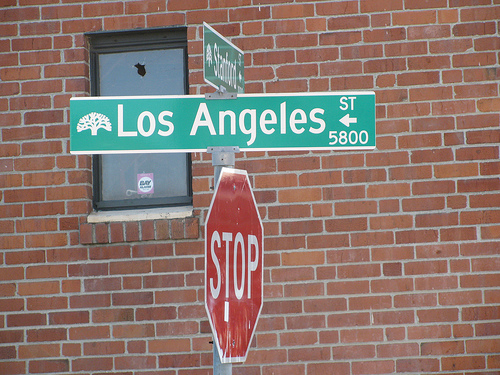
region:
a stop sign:
[202, 210, 267, 320]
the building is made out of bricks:
[316, 170, 473, 318]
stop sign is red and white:
[196, 179, 281, 361]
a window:
[96, 61, 180, 89]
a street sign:
[75, 96, 378, 148]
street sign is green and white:
[67, 102, 394, 154]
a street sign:
[197, 25, 264, 88]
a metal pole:
[212, 355, 224, 373]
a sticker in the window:
[129, 174, 166, 194]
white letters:
[208, 235, 264, 303]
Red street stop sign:
[203, 170, 275, 362]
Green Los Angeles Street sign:
[68, 91, 381, 152]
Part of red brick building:
[265, 33, 340, 70]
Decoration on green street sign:
[75, 107, 114, 137]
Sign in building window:
[133, 170, 155, 195]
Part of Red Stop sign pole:
[213, 358, 228, 373]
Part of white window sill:
[86, 207, 196, 220]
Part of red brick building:
[43, 334, 148, 371]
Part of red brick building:
[276, 312, 343, 351]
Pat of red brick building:
[386, 314, 463, 350]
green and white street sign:
[63, 21, 379, 155]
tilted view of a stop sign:
[197, 159, 268, 358]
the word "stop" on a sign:
[209, 230, 259, 303]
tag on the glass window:
[136, 170, 154, 199]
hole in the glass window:
[131, 58, 147, 81]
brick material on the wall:
[271, 174, 495, 372]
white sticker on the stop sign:
[223, 298, 230, 322]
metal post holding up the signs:
[207, 344, 234, 373]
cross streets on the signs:
[66, 27, 377, 154]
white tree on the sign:
[73, 111, 110, 138]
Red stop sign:
[188, 167, 300, 369]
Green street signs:
[42, 19, 403, 162]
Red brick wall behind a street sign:
[0, 0, 498, 373]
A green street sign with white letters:
[60, 88, 387, 157]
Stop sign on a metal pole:
[193, 138, 271, 374]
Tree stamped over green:
[70, 86, 115, 158]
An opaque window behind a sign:
[85, 21, 196, 213]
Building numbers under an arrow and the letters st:
[325, 90, 380, 154]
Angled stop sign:
[201, 163, 278, 373]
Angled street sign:
[193, 20, 257, 97]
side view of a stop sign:
[198, 169, 269, 360]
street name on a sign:
[65, 83, 382, 155]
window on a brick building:
[79, 35, 195, 220]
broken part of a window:
[130, 57, 147, 79]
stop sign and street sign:
[70, 22, 380, 373]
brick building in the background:
[3, 1, 497, 372]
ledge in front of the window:
[83, 201, 197, 226]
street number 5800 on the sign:
[324, 127, 372, 148]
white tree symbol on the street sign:
[72, 108, 113, 138]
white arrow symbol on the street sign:
[337, 111, 357, 130]